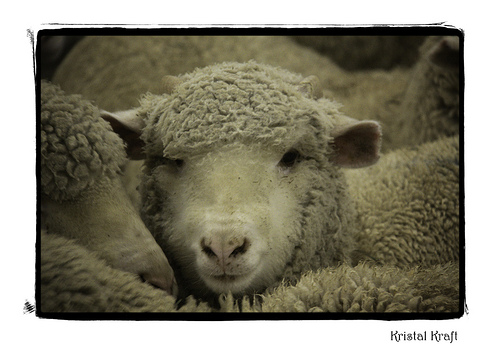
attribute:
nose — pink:
[192, 234, 246, 272]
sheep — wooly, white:
[112, 63, 455, 306]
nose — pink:
[193, 232, 249, 259]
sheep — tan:
[105, 54, 397, 289]